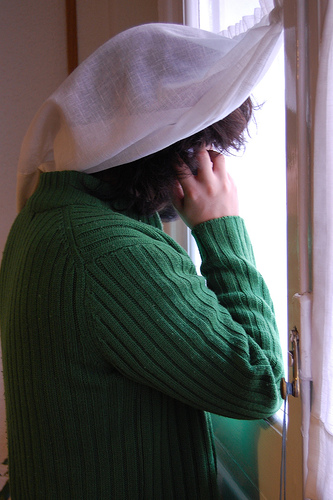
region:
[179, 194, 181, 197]
part of a thumb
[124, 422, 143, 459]
part of a sweater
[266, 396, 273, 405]
elbow of a man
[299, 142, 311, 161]
part of a curtain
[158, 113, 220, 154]
head of a man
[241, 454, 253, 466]
green part on wall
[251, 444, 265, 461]
part of the wall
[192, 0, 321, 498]
white curtains are on the windows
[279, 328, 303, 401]
a handle is on the window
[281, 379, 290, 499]
a blue ribbon is tied to the knob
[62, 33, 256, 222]
the person has dark hair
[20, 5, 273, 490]
the person is under the curtain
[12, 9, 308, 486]
the person is looking out the window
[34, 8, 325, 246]
the man is holding a phone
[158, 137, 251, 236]
the man's hand is at his ear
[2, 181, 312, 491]
the man is wearing a green sweater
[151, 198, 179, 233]
the man has a black beard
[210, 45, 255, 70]
The curtain is white.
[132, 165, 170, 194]
The woman's hair is brown.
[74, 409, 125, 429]
The sweater is green.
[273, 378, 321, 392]
Door knob is gold.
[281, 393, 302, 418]
Blue string hanging from the door knob.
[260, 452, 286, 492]
The door is tan.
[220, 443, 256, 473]
Sweater is casting a shadow.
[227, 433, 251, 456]
The shadow is green.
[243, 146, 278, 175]
Light shining through the window.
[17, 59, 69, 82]
The wall is brown.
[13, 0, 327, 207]
The curtain is white.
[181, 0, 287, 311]
Light shining through the window.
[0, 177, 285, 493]
The person's sweater is green.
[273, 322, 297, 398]
The doorknob is metal.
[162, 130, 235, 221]
The person is holding a phone.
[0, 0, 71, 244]
The wall is white.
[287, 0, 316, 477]
The pole is metal.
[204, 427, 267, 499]
The baseboard is white.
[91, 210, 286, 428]
The woman's sleeve is long.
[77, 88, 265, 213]
The person has long hair.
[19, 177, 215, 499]
The sweater is green.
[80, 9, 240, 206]
Curtain on the head.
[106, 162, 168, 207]
Person has dark hair.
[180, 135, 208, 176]
The person holds something to their ear.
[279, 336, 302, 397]
The door handle is brass.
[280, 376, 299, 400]
The knob for the door.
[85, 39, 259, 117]
The curtain us white.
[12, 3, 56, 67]
The wall is off white.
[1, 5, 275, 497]
A person standing up.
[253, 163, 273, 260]
Light glaring from the window.